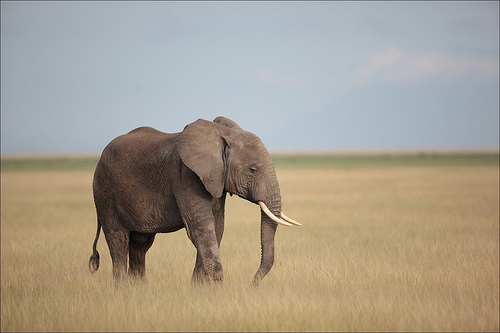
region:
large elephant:
[60, 116, 300, 291]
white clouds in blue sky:
[31, 18, 112, 60]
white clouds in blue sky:
[344, 72, 428, 120]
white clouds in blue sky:
[321, 51, 369, 73]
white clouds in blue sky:
[268, 83, 338, 134]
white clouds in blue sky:
[345, 25, 426, 97]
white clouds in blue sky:
[212, 15, 294, 76]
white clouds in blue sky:
[114, 39, 172, 71]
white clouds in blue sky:
[381, 63, 429, 87]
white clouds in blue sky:
[301, 52, 375, 112]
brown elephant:
[64, 102, 301, 312]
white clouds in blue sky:
[31, 22, 149, 93]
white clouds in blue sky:
[140, 43, 200, 64]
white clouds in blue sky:
[270, 19, 357, 96]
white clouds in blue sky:
[388, 61, 469, 122]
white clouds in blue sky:
[242, 63, 297, 114]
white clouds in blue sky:
[340, 59, 371, 106]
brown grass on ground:
[347, 158, 407, 219]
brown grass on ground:
[348, 257, 406, 292]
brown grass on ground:
[356, 197, 423, 244]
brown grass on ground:
[41, 238, 96, 296]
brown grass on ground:
[49, 199, 87, 236]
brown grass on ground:
[424, 162, 496, 225]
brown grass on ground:
[303, 167, 381, 222]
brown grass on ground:
[409, 167, 456, 208]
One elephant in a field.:
[68, 103, 311, 295]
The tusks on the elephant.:
[251, 188, 305, 233]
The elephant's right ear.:
[181, 111, 233, 198]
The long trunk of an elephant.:
[244, 191, 287, 296]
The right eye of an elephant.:
[241, 158, 265, 178]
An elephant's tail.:
[86, 210, 108, 279]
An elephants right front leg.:
[169, 187, 224, 292]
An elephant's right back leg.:
[99, 218, 131, 289]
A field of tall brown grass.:
[12, 160, 486, 325]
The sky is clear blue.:
[11, 5, 486, 115]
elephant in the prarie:
[69, 105, 304, 314]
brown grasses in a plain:
[341, 174, 478, 320]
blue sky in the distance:
[238, 30, 478, 117]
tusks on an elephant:
[253, 199, 308, 230]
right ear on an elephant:
[176, 116, 229, 196]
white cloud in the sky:
[368, 41, 463, 82]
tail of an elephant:
[80, 206, 100, 278]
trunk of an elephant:
[250, 186, 281, 286]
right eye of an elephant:
[242, 156, 259, 176]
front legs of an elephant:
[178, 205, 238, 290]